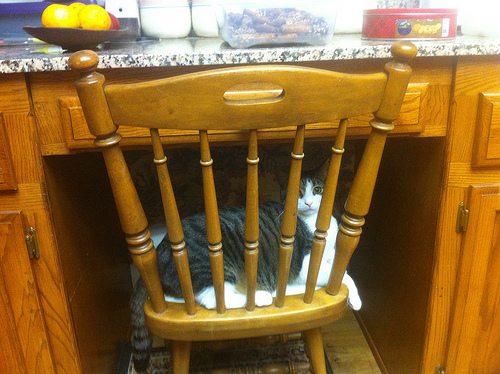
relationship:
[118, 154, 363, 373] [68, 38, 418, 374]
cat on chair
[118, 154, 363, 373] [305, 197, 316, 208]
cat has white nose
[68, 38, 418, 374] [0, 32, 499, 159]
chair at desk top area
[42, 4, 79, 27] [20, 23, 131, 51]
lemon are in bowl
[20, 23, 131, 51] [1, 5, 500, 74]
bowl on counter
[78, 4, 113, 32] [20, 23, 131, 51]
lemon in bowl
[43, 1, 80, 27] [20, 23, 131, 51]
lemon in bowl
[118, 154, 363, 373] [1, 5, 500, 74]
cat sitting under counter top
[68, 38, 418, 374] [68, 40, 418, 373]
chair of wood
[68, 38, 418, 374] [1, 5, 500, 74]
chair under counter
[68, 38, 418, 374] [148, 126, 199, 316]
chair has a baluster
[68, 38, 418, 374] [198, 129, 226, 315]
chair has a baluster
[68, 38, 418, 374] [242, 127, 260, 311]
chair has a baluster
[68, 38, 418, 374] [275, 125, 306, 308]
chair has a baluster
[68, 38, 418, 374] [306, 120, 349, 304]
chair has a baluster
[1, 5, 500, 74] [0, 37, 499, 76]
counter has shelf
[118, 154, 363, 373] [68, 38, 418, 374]
cat sits in a chair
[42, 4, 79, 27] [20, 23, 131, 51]
lemon on a bowl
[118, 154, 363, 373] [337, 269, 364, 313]
cat has white front leg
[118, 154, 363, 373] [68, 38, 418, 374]
cat laying on chair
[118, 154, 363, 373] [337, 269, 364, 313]
cat has a white paw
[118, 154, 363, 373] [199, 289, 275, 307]
cat has a white paw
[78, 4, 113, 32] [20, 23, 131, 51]
lemon on a plate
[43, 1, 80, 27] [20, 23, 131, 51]
lemon on a plate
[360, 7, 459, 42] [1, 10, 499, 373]
tin on desk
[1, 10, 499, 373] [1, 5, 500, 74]
wood desk has a marble top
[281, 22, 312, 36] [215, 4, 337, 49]
cookie in plastic container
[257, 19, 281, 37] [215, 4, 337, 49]
cookie in plastic container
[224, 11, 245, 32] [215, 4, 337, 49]
cookie in plastic container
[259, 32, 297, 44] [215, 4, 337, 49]
cookie in plastic container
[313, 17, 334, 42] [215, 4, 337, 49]
cookie in plastic container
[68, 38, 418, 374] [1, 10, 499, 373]
chair under a desk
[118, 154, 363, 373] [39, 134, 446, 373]
cat on a chair under a desk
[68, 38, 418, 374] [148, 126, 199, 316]
chair has a dowel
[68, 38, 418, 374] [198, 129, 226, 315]
chair has a dowel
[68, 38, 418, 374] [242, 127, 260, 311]
chair has a dowel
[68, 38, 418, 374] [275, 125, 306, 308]
chair has a dowel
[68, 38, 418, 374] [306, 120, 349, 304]
chair has a dowel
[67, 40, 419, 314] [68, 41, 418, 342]
dowels are across back of chair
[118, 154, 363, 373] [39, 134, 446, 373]
cat seated on chair under desk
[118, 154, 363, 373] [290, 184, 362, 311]
cat has solid white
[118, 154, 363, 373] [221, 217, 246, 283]
cat has black stripes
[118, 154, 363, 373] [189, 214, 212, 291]
cat has grey stripes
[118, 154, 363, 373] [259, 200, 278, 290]
cat has black stripes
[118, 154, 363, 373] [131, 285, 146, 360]
cat has grey stripes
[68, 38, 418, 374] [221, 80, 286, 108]
chair has a cutout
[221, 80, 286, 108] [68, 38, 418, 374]
cutout on top of chair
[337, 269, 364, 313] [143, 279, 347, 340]
paw over chair edge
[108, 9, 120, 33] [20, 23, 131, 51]
apple on a plate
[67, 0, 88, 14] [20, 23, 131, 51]
orange on a plate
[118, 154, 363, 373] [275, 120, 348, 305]
cat between two dowels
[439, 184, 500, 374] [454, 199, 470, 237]
cabinet door has hinge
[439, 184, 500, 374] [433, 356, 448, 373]
cabinet door has hinge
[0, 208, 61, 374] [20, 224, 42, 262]
cabinet door has hinge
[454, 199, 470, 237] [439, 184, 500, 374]
hinge connected to cabinet door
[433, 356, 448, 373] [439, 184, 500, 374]
hinge connected to cabinet door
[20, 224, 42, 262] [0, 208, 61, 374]
hinge connected to cabinet door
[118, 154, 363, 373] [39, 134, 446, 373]
kitty hiding under a desk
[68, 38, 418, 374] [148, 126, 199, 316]
chair has a spindle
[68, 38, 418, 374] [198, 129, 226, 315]
chair has a spindle